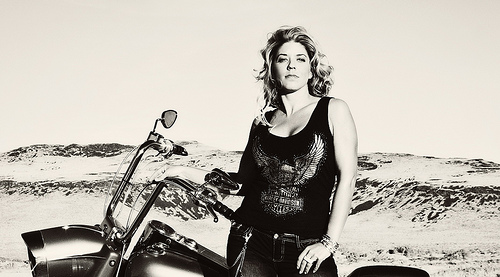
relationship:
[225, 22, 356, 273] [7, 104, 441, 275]
woman on motorcycle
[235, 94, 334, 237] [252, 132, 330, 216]
tank top on eagle design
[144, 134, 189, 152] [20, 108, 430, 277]
handle on motorcycle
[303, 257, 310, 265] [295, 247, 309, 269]
ring on finger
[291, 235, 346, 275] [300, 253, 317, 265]
hand wearing rings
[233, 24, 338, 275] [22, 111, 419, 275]
woman standing next to motorcycle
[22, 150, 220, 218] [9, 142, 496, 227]
snow on hill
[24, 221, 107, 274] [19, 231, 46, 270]
cover of light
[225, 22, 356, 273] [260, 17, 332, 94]
woman with hair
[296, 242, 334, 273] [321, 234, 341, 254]
hand with bracelet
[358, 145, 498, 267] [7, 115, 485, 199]
mountains in distance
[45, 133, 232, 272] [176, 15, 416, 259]
motorcycle behind woman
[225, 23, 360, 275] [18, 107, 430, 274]
person and vehicle